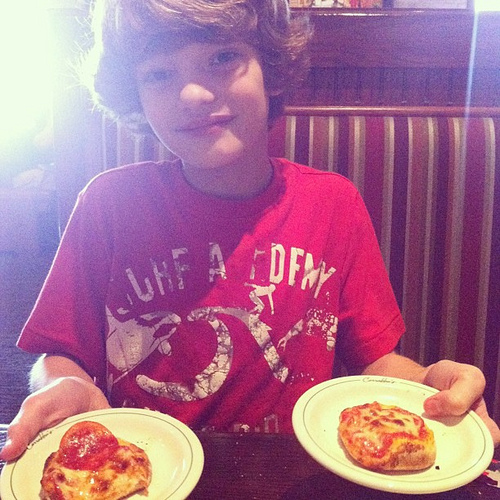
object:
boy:
[0, 0, 499, 462]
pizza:
[337, 400, 438, 473]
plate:
[290, 375, 495, 495]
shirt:
[14, 155, 406, 433]